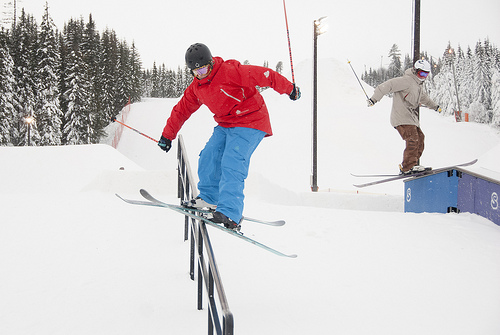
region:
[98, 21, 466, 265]
two people skiing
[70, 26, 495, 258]
two people doing tricks while skiing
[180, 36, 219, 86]
black helmet on skiers head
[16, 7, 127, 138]
tall trees covered with snow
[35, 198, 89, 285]
ground covered with white snow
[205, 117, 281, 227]
blue ski pants worn by skier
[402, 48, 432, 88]
white helmet worn by skier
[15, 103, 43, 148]
light in background before trees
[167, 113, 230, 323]
black metal railing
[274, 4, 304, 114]
ski poles in skiers hand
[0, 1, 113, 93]
trees covered with snow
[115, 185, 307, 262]
silver skis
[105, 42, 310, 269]
skier doing guard rail trick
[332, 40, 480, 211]
skier jumping in air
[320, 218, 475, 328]
ground covered in snow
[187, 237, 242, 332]
silver metal guard rail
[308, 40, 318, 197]
black metal light pole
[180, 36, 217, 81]
skier in black safety helmet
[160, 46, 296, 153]
skier in red jacket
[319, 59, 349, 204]
large hill of snow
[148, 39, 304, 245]
a man skiing on ice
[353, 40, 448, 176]
a man skiing on ice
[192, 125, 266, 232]
the man is wearing blue pants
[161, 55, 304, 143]
the man is wearing a red jacket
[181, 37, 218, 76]
the man is wearing a black helmet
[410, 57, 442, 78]
the man is wearing a white helmet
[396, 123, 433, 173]
the man is wearing a brown trouser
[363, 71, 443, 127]
the man is wearing a grey jacket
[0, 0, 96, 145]
pine trees on the background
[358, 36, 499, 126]
pine trees on the background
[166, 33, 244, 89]
the man's helmet is black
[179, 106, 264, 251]
the pants are blue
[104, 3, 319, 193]
the man is holding ski poles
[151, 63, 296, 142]
the jacket is red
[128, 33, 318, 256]
the man is skiing on a rail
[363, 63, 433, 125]
the man's jacket is brown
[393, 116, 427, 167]
the man's pants are brown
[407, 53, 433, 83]
the helmet is white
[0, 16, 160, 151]
the trees are covered in snow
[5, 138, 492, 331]
the ground is covered in snow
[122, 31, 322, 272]
man skiing on a rail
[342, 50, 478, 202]
man skiing in the air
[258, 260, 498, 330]
white snow on the ground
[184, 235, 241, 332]
black rail in the snow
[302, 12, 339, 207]
light on a pole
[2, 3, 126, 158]
trees with snow behind hill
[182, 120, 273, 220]
blue snowpants on a skier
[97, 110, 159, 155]
ski pole in skiers hand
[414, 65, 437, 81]
red goggles on skiers head